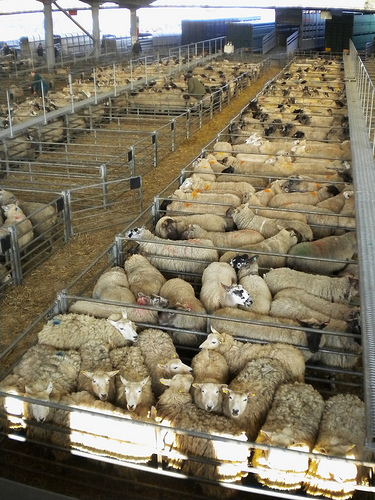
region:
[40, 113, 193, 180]
empty animal pens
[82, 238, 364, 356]
an animal pen filled with sheep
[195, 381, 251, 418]
the faces of two sheep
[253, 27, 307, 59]
a ramp for loading animals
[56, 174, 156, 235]
the gate to an open animal pen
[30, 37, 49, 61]
a man in a large building that holds sheep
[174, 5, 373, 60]
a loading dock near some animal pens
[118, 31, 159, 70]
a man walking near some pens filled with sheep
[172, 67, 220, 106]
a man feeding sheep held in pens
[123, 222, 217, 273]
a sheep in a pen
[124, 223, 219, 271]
sheep in a small pen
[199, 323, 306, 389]
sheep in a small pen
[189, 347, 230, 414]
sheep in a small pen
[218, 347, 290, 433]
sheep in a small pen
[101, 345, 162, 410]
sheep in a small pen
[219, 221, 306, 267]
sheep in a small pen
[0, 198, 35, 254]
sheep in a small pen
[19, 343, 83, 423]
sheep in a small pen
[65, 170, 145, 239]
large metal tube gate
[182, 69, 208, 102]
person wearing a green coat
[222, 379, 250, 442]
A sheep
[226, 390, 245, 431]
A sheep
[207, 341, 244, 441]
A sheep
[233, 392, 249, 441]
A sheep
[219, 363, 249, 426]
A sheep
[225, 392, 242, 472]
A sheep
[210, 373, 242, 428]
A sheep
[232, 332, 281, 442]
A sheep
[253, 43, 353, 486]
Sheep hearded in cages.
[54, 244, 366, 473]
Sheep crammed together uncomfertably.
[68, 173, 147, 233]
The fence is open.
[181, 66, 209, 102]
The man has a green jacket.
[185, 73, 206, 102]
A man bends over slightly.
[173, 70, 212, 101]
A man in the pen.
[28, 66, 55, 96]
A person bends slightly.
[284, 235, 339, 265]
Colored marking on the back.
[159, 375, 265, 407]
Yellow tags on their ears.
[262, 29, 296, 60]
A ramp to the truck.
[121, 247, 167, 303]
sheep in a small pen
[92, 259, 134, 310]
sheep in a small pen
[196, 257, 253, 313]
sheep in a small pen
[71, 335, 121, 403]
sheep in a small pen